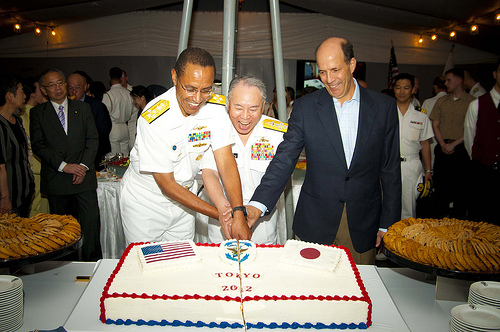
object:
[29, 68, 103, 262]
people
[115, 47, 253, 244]
men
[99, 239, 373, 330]
cake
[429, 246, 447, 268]
cookies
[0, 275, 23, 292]
plates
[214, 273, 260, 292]
tokyo 2012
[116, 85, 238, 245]
uniforms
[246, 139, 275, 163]
awards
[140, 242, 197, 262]
flag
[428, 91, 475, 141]
shirt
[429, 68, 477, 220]
soldier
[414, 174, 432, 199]
hat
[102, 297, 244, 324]
icing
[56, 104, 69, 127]
tie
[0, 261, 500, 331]
table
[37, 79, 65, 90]
glasses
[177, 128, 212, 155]
chest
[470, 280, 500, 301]
plate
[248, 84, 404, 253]
jacket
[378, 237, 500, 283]
tray